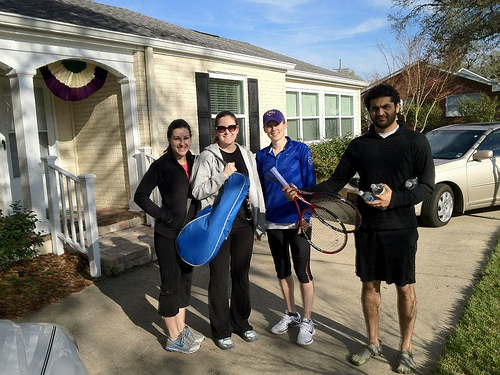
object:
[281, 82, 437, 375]
man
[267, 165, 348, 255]
rackets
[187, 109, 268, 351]
woman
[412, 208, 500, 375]
driveway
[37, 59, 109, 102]
bunting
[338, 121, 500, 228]
car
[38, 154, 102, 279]
rail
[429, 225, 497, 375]
grass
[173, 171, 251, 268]
bag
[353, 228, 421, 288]
shorts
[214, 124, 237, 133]
sunglasses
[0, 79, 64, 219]
door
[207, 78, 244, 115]
shutters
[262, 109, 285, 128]
cap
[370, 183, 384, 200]
water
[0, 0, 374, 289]
house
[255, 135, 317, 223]
shirt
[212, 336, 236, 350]
shoes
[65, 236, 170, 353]
shadows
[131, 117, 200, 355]
people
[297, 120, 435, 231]
outfit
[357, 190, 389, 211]
bottles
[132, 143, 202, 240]
outfit